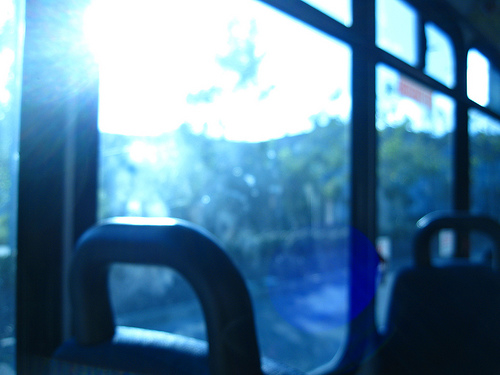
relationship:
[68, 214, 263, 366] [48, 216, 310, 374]
headrest of bus seat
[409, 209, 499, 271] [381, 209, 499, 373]
headrest of bus seat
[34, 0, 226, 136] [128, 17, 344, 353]
sun ray in window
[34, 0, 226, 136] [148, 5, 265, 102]
sun ray of sun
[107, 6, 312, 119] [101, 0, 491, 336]
sun ray in window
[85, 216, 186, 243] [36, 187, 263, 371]
top of seat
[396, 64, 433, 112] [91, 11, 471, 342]
sticker on window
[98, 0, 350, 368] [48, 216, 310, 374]
window beside bus seat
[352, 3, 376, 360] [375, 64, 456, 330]
metal beside window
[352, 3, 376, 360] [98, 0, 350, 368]
metal beside window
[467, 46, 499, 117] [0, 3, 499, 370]
window on bus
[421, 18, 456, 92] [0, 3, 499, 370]
window on bus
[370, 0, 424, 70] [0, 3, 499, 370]
window on bus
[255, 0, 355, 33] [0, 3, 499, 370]
window on bus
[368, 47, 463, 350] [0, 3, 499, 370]
window on bus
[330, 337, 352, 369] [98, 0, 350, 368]
grommet holding window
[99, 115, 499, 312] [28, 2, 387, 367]
shrubs outside window